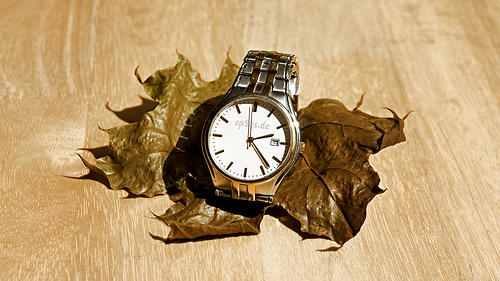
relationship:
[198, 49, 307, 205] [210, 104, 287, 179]
watch indicating 2:24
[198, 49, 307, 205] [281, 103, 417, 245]
watch sitting on leaf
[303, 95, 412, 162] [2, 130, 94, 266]
leaf sitting on surface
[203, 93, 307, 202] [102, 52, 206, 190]
watch sitting on leaf